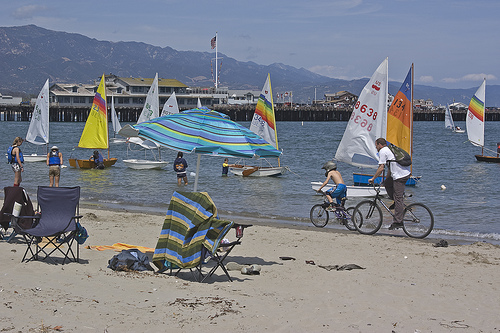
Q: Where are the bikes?
A: On beach.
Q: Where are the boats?
A: In water.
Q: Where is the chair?
A: On beach.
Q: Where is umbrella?
A: On beach.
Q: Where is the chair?
A: In sand.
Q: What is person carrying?
A: Backpack.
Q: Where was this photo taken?
A: Beach.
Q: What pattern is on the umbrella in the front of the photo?
A: Stripe.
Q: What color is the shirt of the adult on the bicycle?
A: White.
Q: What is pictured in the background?
A: Mountain.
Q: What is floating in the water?
A: Sailboats.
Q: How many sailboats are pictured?
A: Eleven.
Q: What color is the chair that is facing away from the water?
A: Blue.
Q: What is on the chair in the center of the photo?
A: Towel.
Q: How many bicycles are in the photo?
A: Two.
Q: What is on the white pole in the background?
A: A flag.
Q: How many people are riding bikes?
A: Two.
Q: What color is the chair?
A: Grey.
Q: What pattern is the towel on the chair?
A: Striped.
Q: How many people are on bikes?
A: Two.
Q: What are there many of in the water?
A: Sailboats.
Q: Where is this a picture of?
A: The beach.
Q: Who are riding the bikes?
A: A man and child.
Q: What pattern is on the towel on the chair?
A: Stripes.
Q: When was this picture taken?
A: Daytime.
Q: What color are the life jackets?
A: Blue.